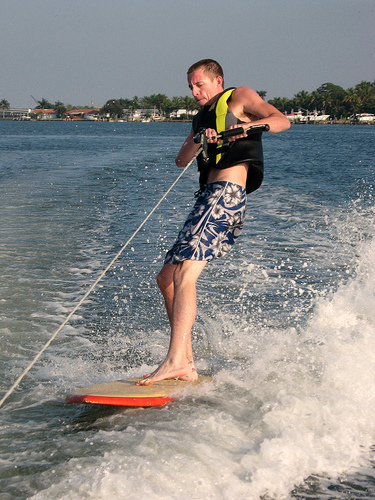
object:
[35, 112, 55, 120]
wall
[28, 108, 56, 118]
building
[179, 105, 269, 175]
vest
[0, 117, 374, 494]
water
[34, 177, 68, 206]
water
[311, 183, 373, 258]
splash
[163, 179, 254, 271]
shorts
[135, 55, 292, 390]
man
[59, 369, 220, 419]
surfboard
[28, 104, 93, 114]
roofs